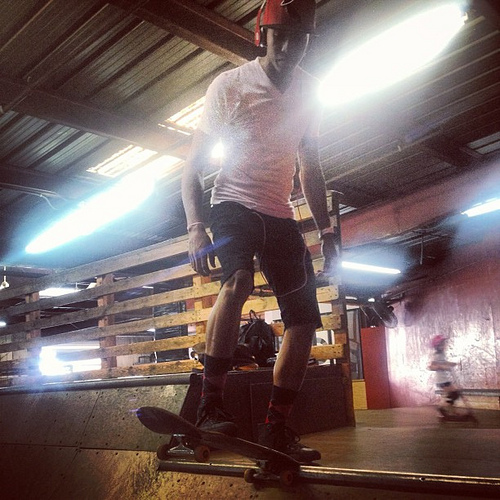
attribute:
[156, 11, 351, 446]
man — young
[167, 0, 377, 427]
man — young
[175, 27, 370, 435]
man — young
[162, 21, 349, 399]
man — young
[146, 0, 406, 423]
man — young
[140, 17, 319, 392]
man — young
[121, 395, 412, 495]
skateboard — black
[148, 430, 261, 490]
wheels — black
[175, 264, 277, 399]
leg — muscular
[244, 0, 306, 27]
helmet — red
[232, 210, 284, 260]
cord — white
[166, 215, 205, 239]
watch — white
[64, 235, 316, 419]
fence — large, wooden, brown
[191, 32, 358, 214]
shirt — white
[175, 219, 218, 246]
band — white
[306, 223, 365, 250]
watch — white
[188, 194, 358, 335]
shorts — black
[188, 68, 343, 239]
shirt — v-neck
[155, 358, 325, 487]
socks — black, red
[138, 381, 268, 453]
shoes — black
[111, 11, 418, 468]
man — young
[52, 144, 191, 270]
light — bright, ceiling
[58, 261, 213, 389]
railing — wooden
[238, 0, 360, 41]
helmet — red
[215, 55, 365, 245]
shirt — white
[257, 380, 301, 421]
sock — black, red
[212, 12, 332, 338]
young man — ready to skateboard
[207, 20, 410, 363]
young man — ready to skateboard